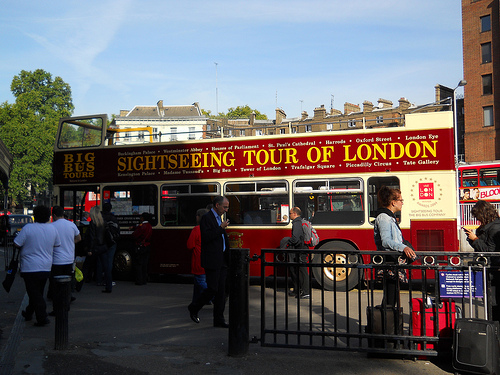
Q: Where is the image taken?
A: On road.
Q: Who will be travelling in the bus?
A: People.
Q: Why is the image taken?
A: Remembrance.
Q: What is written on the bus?
A: SIGHTSEEING TOUR OF LONDON.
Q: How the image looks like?
A: Pretty good.